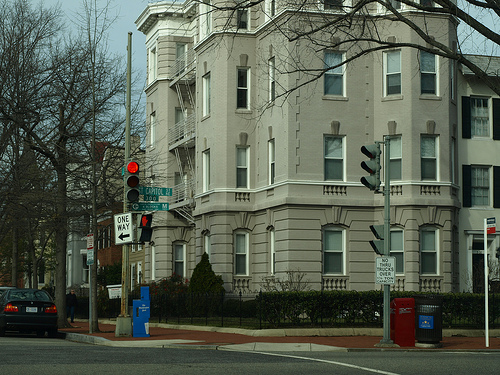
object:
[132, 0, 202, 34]
design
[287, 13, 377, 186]
wall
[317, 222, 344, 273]
window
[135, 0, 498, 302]
building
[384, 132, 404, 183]
window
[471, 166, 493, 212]
window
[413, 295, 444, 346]
bin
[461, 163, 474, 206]
shutter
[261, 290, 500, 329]
hedge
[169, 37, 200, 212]
staircases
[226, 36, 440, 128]
branches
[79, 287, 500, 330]
railing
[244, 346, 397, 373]
line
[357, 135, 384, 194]
traffic signals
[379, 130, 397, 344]
pole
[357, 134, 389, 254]
street lights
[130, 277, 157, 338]
box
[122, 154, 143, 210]
traffic light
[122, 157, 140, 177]
stop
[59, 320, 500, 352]
sidewalk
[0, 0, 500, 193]
sky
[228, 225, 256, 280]
windows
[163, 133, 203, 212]
balconies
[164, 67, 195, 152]
escapes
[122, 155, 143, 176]
signal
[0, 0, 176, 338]
tree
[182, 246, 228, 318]
tree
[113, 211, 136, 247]
sign board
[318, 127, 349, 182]
window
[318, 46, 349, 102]
window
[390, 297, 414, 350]
box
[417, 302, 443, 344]
stand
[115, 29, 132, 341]
pole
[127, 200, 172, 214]
signs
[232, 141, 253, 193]
windows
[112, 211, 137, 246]
sign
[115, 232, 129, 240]
arrow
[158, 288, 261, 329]
fence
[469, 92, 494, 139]
window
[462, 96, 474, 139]
shutters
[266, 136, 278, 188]
windows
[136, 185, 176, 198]
signs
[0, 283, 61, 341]
car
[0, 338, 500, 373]
road